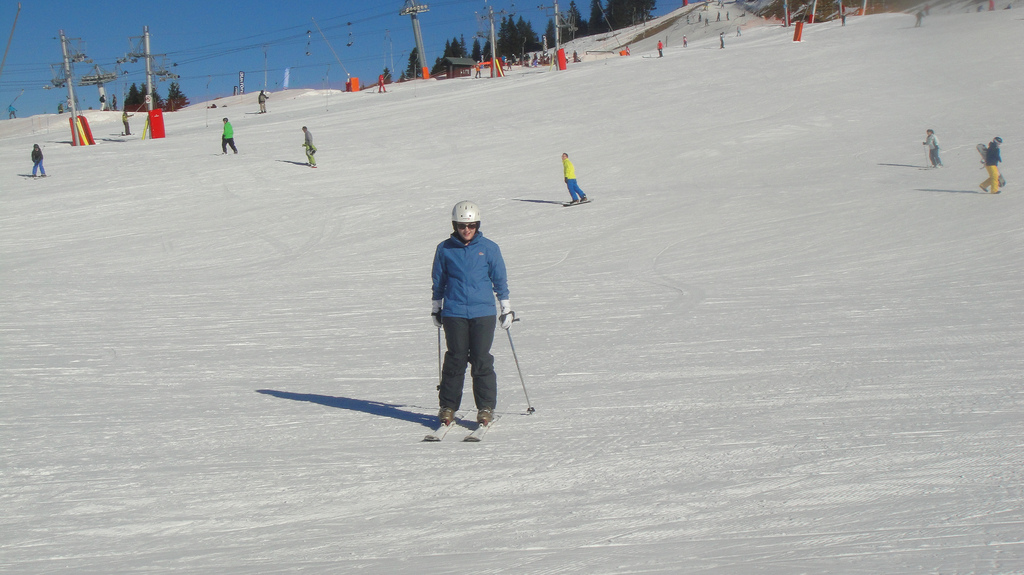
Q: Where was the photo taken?
A: On a mountain.